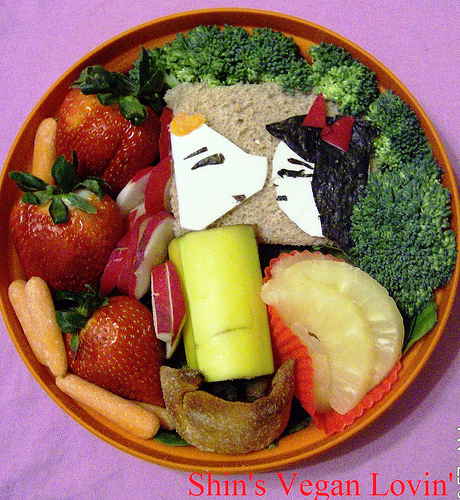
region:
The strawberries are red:
[9, 179, 124, 283]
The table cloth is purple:
[12, 408, 114, 498]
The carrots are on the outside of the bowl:
[49, 360, 177, 446]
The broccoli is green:
[369, 152, 455, 265]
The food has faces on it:
[172, 99, 357, 236]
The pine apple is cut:
[265, 260, 424, 413]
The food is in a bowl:
[7, 274, 448, 491]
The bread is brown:
[157, 70, 317, 163]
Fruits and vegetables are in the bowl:
[41, 331, 285, 477]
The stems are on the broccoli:
[7, 144, 125, 234]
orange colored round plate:
[28, 30, 413, 496]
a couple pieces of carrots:
[26, 285, 155, 457]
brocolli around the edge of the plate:
[198, 18, 451, 265]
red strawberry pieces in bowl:
[48, 127, 162, 361]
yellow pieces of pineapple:
[177, 242, 278, 396]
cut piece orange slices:
[291, 252, 414, 426]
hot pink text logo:
[186, 472, 458, 488]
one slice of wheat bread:
[178, 81, 325, 248]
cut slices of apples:
[108, 200, 211, 373]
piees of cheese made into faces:
[167, 110, 364, 207]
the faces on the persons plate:
[161, 110, 376, 241]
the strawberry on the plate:
[68, 294, 167, 409]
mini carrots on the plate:
[5, 277, 79, 381]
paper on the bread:
[175, 83, 335, 247]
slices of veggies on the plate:
[113, 173, 182, 336]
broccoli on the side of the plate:
[354, 100, 450, 306]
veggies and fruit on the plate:
[10, 168, 159, 408]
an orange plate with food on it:
[1, 6, 432, 461]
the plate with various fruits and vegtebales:
[0, 3, 458, 472]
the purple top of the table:
[12, 0, 50, 90]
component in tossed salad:
[152, 265, 176, 330]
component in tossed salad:
[81, 311, 153, 390]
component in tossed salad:
[56, 382, 150, 435]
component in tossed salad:
[367, 194, 433, 281]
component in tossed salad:
[192, 234, 258, 372]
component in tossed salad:
[35, 195, 103, 251]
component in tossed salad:
[148, 165, 172, 203]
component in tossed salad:
[273, 293, 369, 395]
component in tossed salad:
[171, 389, 289, 441]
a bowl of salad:
[52, 33, 404, 480]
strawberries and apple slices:
[15, 171, 168, 278]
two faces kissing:
[163, 102, 356, 232]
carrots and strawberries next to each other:
[10, 191, 164, 443]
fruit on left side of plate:
[46, 94, 172, 386]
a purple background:
[12, 14, 64, 58]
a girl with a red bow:
[275, 99, 361, 235]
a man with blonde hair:
[167, 108, 259, 212]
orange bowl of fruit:
[27, 14, 449, 424]